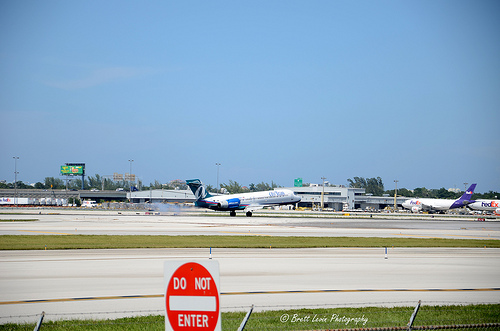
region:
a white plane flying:
[12, 25, 373, 269]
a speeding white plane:
[62, 152, 397, 328]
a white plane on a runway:
[57, 148, 350, 325]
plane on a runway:
[42, 151, 347, 323]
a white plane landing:
[58, 126, 376, 330]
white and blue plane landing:
[39, 72, 427, 278]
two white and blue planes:
[69, 90, 497, 277]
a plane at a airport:
[35, 125, 442, 290]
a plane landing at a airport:
[18, 129, 425, 301]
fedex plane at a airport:
[53, 126, 498, 308]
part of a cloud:
[403, 120, 410, 143]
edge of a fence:
[331, 240, 338, 272]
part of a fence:
[346, 307, 353, 315]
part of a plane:
[255, 190, 260, 197]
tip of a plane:
[299, 180, 306, 197]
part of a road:
[283, 235, 296, 261]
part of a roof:
[108, 200, 122, 209]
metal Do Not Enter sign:
[162, 257, 220, 329]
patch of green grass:
[16, 303, 497, 327]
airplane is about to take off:
[185, 178, 300, 213]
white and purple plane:
[400, 183, 478, 210]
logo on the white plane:
[480, 200, 499, 207]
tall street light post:
[11, 153, 21, 188]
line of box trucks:
[0, 195, 66, 207]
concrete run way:
[2, 246, 494, 321]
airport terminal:
[287, 185, 401, 209]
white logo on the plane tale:
[190, 180, 208, 200]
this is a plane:
[162, 161, 303, 239]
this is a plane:
[401, 189, 498, 244]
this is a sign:
[159, 260, 228, 327]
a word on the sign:
[170, 273, 190, 299]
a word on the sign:
[165, 267, 191, 292]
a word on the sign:
[188, 260, 214, 291]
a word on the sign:
[175, 307, 213, 327]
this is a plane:
[391, 175, 492, 221]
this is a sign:
[47, 142, 107, 198]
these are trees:
[18, 156, 146, 216]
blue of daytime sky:
[3, 2, 497, 178]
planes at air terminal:
[176, 181, 496, 218]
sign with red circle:
[165, 257, 220, 329]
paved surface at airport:
[0, 250, 498, 315]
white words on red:
[173, 272, 210, 329]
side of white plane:
[185, 179, 298, 217]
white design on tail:
[185, 179, 207, 201]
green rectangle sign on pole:
[60, 162, 86, 186]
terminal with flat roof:
[289, 186, 364, 206]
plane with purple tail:
[403, 183, 476, 210]